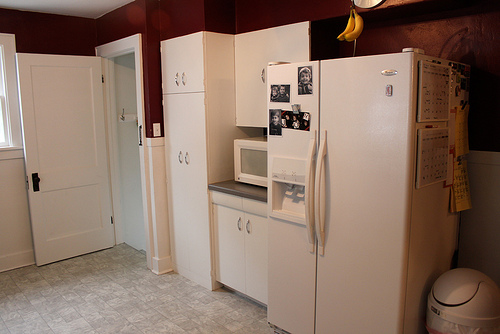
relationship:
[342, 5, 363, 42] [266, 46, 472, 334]
banana on fridge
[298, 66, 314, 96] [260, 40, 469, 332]
pictures are on fridge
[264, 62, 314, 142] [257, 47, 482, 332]
pictures on refrigerator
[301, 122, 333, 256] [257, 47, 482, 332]
handles on refrigerator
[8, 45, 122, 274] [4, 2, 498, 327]
door in kitchen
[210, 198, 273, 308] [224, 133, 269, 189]
doors under microwave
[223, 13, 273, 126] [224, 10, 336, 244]
door to cabinet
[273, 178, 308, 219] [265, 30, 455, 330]
dispenser on fridge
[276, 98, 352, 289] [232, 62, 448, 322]
handles on fridge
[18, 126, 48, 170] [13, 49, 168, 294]
handle on door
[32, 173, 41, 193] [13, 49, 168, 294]
handle on door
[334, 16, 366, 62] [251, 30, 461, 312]
banana on refrigerator